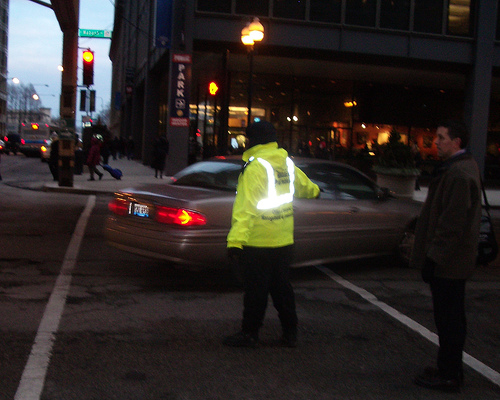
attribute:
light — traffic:
[233, 10, 297, 52]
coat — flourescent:
[225, 142, 320, 248]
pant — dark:
[217, 235, 319, 339]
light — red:
[156, 204, 206, 227]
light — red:
[105, 200, 128, 210]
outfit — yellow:
[217, 140, 324, 254]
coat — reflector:
[229, 147, 321, 256]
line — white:
[11, 189, 100, 397]